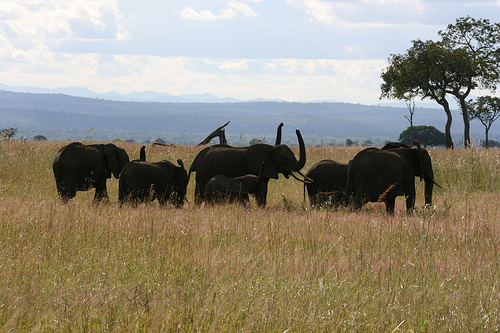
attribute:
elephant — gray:
[347, 149, 437, 218]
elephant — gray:
[192, 135, 314, 210]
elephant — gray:
[118, 164, 189, 208]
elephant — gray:
[49, 144, 136, 206]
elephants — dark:
[60, 127, 442, 211]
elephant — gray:
[194, 139, 316, 199]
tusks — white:
[278, 160, 333, 186]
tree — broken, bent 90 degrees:
[179, 116, 236, 145]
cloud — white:
[177, 0, 256, 21]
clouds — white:
[1, 1, 493, 102]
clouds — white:
[295, 1, 456, 42]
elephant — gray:
[187, 129, 309, 213]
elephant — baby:
[182, 125, 317, 218]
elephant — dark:
[184, 123, 311, 209]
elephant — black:
[49, 138, 130, 217]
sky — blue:
[1, 1, 499, 101]